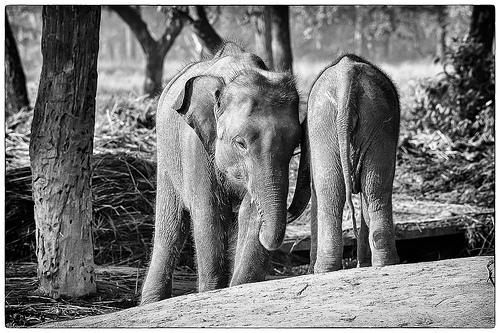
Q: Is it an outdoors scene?
A: Yes, it is outdoors.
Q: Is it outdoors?
A: Yes, it is outdoors.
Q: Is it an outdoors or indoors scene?
A: It is outdoors.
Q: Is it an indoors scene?
A: No, it is outdoors.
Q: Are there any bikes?
A: No, there are no bikes.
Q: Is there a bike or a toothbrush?
A: No, there are no bikes or toothbrushes.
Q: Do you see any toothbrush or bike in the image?
A: No, there are no bikes or toothbrushes.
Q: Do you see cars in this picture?
A: No, there are no cars.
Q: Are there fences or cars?
A: No, there are no cars or fences.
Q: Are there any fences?
A: No, there are no fences.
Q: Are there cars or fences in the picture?
A: No, there are no fences or cars.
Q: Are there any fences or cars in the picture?
A: No, there are no fences or cars.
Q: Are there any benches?
A: No, there are no benches.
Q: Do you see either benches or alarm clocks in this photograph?
A: No, there are no benches or alarm clocks.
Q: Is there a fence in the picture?
A: No, there are no fences.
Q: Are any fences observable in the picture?
A: No, there are no fences.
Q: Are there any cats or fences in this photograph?
A: No, there are no fences or cats.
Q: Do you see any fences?
A: No, there are no fences.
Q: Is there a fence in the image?
A: No, there are no fences.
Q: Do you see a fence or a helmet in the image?
A: No, there are no fences or helmets.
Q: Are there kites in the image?
A: No, there are no kites.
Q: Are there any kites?
A: No, there are no kites.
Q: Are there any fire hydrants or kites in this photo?
A: No, there are no kites or fire hydrants.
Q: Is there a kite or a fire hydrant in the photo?
A: No, there are no kites or fire hydrants.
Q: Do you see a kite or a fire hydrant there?
A: No, there are no kites or fire hydrants.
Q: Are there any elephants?
A: Yes, there is an elephant.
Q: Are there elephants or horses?
A: Yes, there is an elephant.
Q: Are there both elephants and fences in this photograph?
A: No, there is an elephant but no fences.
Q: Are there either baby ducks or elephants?
A: Yes, there is a baby elephant.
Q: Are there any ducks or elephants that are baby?
A: Yes, the elephant is a baby.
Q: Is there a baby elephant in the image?
A: Yes, there is a baby elephant.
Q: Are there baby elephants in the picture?
A: Yes, there is a baby elephant.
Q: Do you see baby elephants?
A: Yes, there is a baby elephant.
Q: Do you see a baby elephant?
A: Yes, there is a baby elephant.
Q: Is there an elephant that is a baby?
A: Yes, there is an elephant that is a baby.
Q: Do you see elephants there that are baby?
A: Yes, there is an elephant that is a baby.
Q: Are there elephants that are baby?
A: Yes, there is an elephant that is a baby.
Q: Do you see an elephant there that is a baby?
A: Yes, there is an elephant that is a baby.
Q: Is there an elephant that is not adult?
A: Yes, there is an baby elephant.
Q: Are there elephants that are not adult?
A: Yes, there is an baby elephant.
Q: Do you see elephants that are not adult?
A: Yes, there is an baby elephant.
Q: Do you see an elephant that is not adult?
A: Yes, there is an baby elephant.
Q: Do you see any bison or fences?
A: No, there are no fences or bison.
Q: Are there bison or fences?
A: No, there are no fences or bison.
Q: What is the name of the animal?
A: The animal is an elephant.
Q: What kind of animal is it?
A: The animal is an elephant.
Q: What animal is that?
A: This is an elephant.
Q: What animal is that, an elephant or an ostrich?
A: This is an elephant.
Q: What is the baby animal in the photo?
A: The animal is an elephant.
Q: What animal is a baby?
A: The animal is an elephant.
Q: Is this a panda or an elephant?
A: This is an elephant.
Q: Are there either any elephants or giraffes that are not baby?
A: No, there is an elephant but it is a baby.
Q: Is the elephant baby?
A: Yes, the elephant is a baby.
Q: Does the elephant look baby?
A: Yes, the elephant is a baby.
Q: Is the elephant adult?
A: No, the elephant is a baby.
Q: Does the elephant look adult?
A: No, the elephant is a baby.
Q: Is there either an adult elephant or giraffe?
A: No, there is an elephant but it is a baby.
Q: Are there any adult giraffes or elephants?
A: No, there is an elephant but it is a baby.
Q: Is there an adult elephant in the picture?
A: No, there is an elephant but it is a baby.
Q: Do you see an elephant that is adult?
A: No, there is an elephant but it is a baby.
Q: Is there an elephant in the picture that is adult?
A: No, there is an elephant but it is a baby.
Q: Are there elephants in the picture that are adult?
A: No, there is an elephant but it is a baby.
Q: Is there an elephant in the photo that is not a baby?
A: No, there is an elephant but it is a baby.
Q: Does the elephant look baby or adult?
A: The elephant is a baby.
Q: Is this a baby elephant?
A: Yes, this is a baby elephant.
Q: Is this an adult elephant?
A: No, this is a baby elephant.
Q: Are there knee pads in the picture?
A: No, there are no knee pads.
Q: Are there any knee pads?
A: No, there are no knee pads.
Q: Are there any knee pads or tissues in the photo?
A: No, there are no knee pads or tissues.